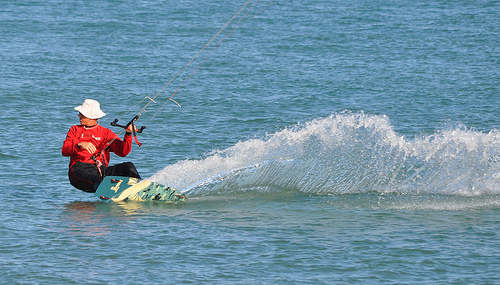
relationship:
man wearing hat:
[65, 94, 142, 192] [73, 98, 106, 119]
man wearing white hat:
[65, 94, 142, 192] [74, 100, 105, 121]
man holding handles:
[65, 94, 142, 192] [110, 114, 146, 133]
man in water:
[65, 94, 142, 192] [2, 1, 500, 284]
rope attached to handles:
[137, 1, 249, 115] [110, 114, 146, 133]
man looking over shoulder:
[65, 94, 142, 192] [66, 124, 84, 137]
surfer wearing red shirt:
[61, 99, 141, 193] [61, 124, 132, 165]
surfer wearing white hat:
[61, 99, 141, 193] [74, 100, 105, 121]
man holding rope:
[65, 94, 142, 192] [137, 1, 249, 115]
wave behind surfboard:
[144, 107, 499, 214] [94, 172, 184, 202]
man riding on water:
[65, 94, 142, 192] [2, 1, 500, 284]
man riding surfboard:
[65, 94, 142, 192] [94, 172, 184, 202]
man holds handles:
[65, 94, 142, 192] [110, 114, 146, 133]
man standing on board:
[65, 94, 142, 192] [93, 175, 188, 206]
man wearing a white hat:
[65, 94, 142, 192] [74, 100, 105, 121]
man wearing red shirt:
[65, 94, 142, 192] [61, 124, 132, 165]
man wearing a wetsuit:
[65, 94, 142, 192] [61, 124, 141, 192]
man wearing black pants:
[65, 94, 142, 192] [68, 162, 141, 194]